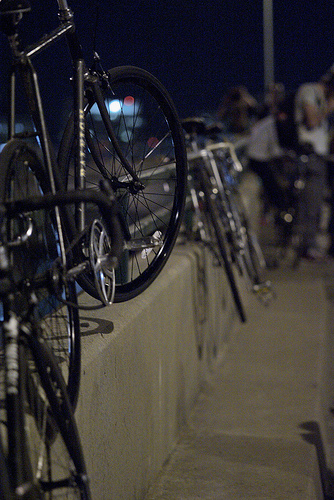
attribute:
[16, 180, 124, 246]
handles — black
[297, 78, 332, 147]
shirt — white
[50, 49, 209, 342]
front tire — black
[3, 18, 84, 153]
frame — black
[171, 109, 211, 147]
seat — black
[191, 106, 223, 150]
seat — black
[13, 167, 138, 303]
handlebar — black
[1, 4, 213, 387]
bike — black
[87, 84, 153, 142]
lights — blurry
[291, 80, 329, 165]
shirt — white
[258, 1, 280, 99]
light post — tall